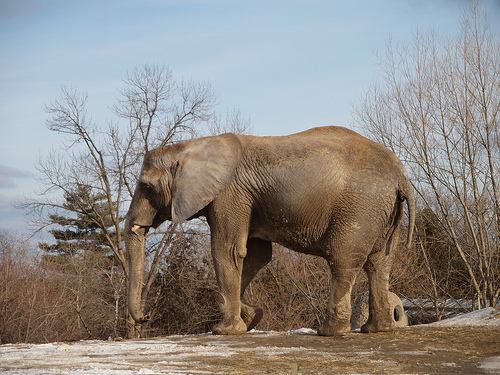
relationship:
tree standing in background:
[33, 180, 130, 272] [0, 59, 480, 342]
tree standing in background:
[9, 60, 222, 339] [0, 59, 480, 342]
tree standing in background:
[152, 223, 223, 333] [0, 59, 480, 342]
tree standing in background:
[416, 204, 475, 294] [0, 59, 480, 342]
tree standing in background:
[350, 1, 485, 307] [0, 59, 480, 342]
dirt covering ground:
[0, 303, 484, 373] [0, 304, 483, 373]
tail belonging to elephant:
[398, 170, 418, 250] [120, 122, 418, 337]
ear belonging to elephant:
[168, 130, 243, 224] [120, 122, 418, 337]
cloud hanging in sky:
[2, 165, 33, 187] [1, 1, 484, 248]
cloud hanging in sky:
[1, 193, 64, 223] [1, 1, 484, 248]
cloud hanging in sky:
[171, 220, 211, 230] [1, 1, 484, 248]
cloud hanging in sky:
[0, 217, 71, 247] [1, 1, 484, 248]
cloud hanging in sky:
[6, 35, 131, 74] [1, 1, 484, 248]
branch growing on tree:
[37, 240, 77, 252] [35, 178, 127, 276]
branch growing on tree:
[45, 210, 85, 224] [35, 178, 127, 276]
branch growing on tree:
[60, 201, 77, 211] [35, 178, 127, 276]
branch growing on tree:
[81, 189, 112, 202] [35, 178, 127, 276]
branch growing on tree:
[82, 241, 113, 254] [35, 178, 127, 276]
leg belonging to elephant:
[204, 198, 251, 336] [120, 122, 418, 337]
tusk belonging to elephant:
[130, 222, 140, 232] [120, 122, 418, 337]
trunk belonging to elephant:
[120, 215, 147, 323] [120, 122, 418, 337]